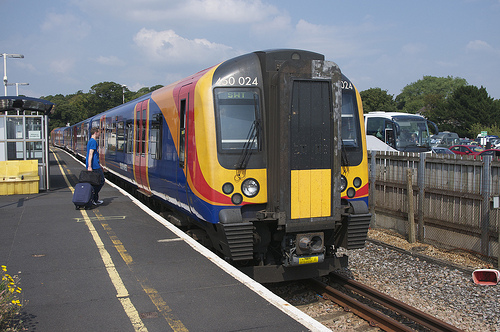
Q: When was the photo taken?
A: Daytime.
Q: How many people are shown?
A: One.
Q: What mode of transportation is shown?
A: Train.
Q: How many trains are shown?
A: 1.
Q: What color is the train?
A: Yellow, blue, red, and orange.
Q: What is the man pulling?
A: Luggage.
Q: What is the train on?
A: Tracks.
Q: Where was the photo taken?
A: At a train station.